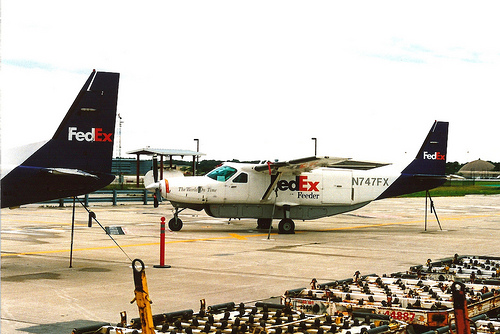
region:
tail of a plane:
[31, 68, 118, 173]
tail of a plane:
[406, 120, 447, 168]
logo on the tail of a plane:
[418, 150, 443, 160]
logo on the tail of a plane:
[66, 126, 111, 141]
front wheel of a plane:
[167, 215, 183, 230]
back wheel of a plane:
[278, 219, 298, 235]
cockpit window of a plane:
[210, 162, 235, 182]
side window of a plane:
[233, 171, 246, 182]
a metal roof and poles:
[128, 145, 204, 183]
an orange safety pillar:
[154, 216, 171, 269]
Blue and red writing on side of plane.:
[270, 175, 349, 208]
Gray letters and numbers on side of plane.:
[338, 168, 390, 191]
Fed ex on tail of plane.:
[421, 140, 473, 177]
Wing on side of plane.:
[258, 125, 341, 182]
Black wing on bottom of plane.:
[274, 217, 292, 229]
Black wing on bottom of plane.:
[251, 208, 273, 230]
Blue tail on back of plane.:
[53, 100, 115, 192]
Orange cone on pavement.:
[149, 213, 181, 274]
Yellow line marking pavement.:
[8, 233, 66, 268]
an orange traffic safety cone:
[152, 215, 168, 267]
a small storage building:
[125, 145, 201, 170]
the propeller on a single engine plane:
[147, 151, 162, 209]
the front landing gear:
[167, 202, 185, 231]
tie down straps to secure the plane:
[421, 187, 446, 233]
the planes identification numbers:
[350, 172, 391, 189]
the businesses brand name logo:
[66, 126, 113, 144]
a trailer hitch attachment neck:
[130, 257, 155, 332]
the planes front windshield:
[208, 163, 239, 182]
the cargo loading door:
[317, 170, 354, 205]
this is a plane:
[157, 130, 457, 231]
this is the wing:
[284, 148, 357, 174]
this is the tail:
[54, 65, 136, 169]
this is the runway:
[201, 235, 265, 295]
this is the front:
[142, 170, 199, 207]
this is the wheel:
[273, 216, 299, 235]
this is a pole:
[157, 213, 170, 265]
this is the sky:
[292, 57, 387, 104]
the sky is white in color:
[293, 40, 380, 96]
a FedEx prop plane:
[152, 119, 452, 231]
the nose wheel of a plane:
[168, 215, 184, 228]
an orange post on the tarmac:
[155, 215, 165, 265]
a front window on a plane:
[207, 165, 233, 177]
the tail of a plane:
[400, 116, 445, 187]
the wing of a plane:
[255, 150, 347, 175]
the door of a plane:
[220, 165, 245, 210]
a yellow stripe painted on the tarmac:
[0, 231, 230, 256]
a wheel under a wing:
[274, 216, 295, 234]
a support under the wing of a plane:
[260, 167, 284, 200]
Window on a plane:
[231, 170, 251, 185]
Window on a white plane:
[234, 170, 250, 185]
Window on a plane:
[208, 161, 235, 182]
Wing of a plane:
[261, 153, 357, 180]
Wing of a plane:
[264, 150, 354, 184]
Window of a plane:
[208, 160, 235, 186]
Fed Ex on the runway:
[148, 120, 465, 240]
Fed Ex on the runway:
[2, 56, 127, 228]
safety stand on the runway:
[148, 213, 175, 272]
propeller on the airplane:
[142, 147, 162, 213]